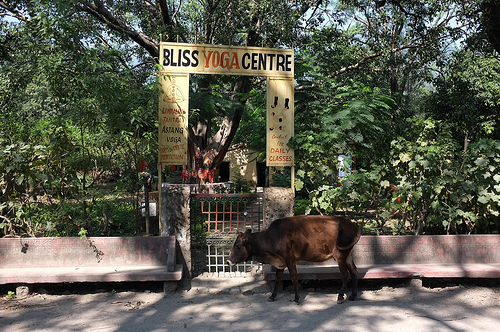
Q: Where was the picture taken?
A: Outside Bliss Yoga Center.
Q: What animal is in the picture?
A: Calf.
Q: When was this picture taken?
A: During the day.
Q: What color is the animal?
A: Brown.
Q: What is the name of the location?
A: Bliss Yoga Center.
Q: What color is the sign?
A: Yellow.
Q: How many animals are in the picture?
A: One.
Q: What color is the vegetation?
A: Green.